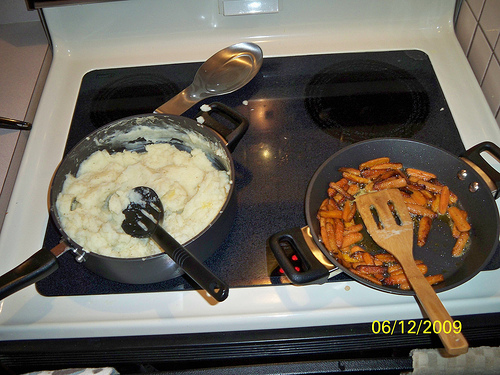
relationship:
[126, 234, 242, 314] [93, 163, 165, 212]
plastic spoon in potato